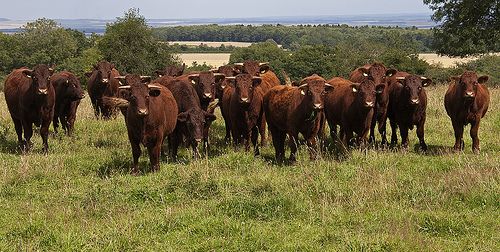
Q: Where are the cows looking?
A: At camera.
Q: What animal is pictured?
A: Cows.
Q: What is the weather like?
A: Clear.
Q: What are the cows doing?
A: Standing.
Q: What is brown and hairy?
A: The cows.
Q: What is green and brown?
A: The grass.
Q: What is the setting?
A: A ranch.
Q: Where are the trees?
A: Behind the cows.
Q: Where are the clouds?
A: Not in the sky.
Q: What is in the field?
A: Cows.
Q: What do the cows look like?
A: Brown.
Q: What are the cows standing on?
A: Grass.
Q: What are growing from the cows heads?
A: Horns.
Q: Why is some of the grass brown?
A: It is dead.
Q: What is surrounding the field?
A: Trees.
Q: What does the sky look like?
A: Blue.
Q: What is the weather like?
A: Sunny.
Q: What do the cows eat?
A: Grass.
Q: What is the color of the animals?
A: Is brown.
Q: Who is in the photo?
A: Animals.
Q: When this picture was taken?
A: During the day.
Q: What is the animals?
A: Bulls.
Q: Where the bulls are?
A: In a camp.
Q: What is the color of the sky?
A: Blue.